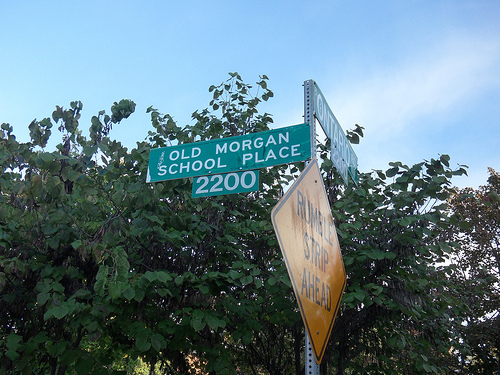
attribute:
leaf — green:
[68, 176, 101, 202]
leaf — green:
[126, 180, 146, 192]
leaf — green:
[133, 187, 154, 209]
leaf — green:
[151, 269, 172, 283]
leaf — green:
[144, 268, 159, 283]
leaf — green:
[115, 97, 129, 111]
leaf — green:
[398, 188, 410, 199]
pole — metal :
[302, 78, 318, 373]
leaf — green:
[397, 164, 429, 191]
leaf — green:
[49, 303, 65, 318]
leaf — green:
[180, 238, 230, 278]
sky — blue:
[0, 1, 496, 154]